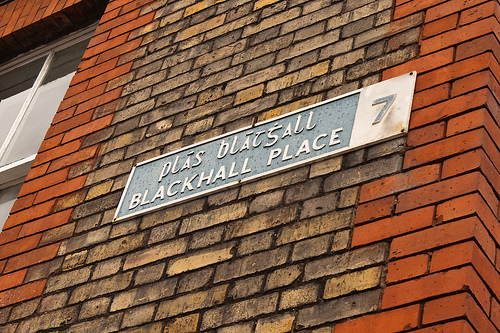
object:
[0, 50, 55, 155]
lines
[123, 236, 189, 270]
brick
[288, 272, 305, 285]
crack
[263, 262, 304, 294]
brick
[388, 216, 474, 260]
brick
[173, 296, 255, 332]
bricks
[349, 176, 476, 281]
bricks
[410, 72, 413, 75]
bolt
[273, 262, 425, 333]
bricks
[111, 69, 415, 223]
sign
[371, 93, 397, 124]
number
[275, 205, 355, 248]
brick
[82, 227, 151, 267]
brick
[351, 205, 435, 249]
brick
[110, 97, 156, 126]
brick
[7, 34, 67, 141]
window frame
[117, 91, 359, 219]
lettering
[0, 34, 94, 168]
pane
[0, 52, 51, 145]
pane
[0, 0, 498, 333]
wall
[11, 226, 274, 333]
bricks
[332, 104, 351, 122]
specks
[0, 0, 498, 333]
building front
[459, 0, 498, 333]
corner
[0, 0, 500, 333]
building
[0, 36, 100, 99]
shadow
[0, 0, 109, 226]
window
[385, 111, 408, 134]
mark